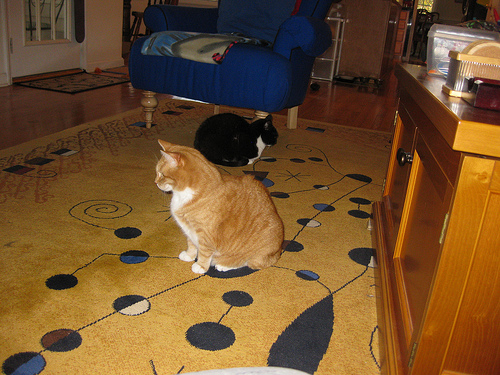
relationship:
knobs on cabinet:
[394, 149, 412, 165] [372, 63, 499, 373]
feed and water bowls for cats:
[334, 70, 382, 88] [153, 112, 284, 276]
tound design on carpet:
[185, 323, 233, 350] [0, 101, 392, 373]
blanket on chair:
[142, 32, 255, 65] [129, 0, 331, 130]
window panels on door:
[26, 0, 72, 42] [5, 0, 82, 80]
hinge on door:
[7, 37, 14, 55] [5, 0, 82, 80]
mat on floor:
[17, 71, 127, 95] [0, 68, 394, 164]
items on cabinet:
[426, 22, 499, 109] [372, 63, 499, 373]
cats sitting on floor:
[153, 112, 284, 276] [0, 68, 394, 164]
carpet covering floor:
[0, 101, 392, 373] [0, 68, 394, 164]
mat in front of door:
[17, 71, 127, 95] [5, 0, 82, 80]